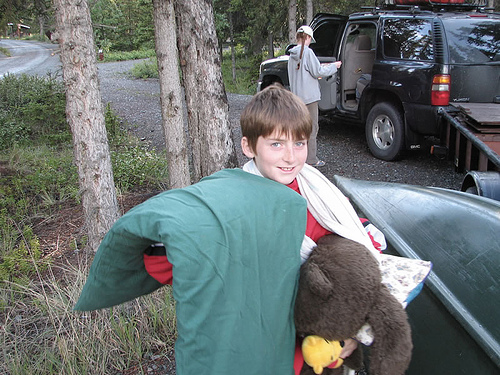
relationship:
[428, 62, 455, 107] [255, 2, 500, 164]
lights on van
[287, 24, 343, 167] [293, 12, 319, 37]
girl wearing hat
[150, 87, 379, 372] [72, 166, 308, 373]
boy holding pillow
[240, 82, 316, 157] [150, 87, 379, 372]
hair on boy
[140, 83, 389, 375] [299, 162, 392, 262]
boy has sheet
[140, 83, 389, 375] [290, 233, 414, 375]
boy holding bear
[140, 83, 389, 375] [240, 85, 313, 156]
boy with hair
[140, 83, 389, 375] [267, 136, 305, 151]
boy with blue eyes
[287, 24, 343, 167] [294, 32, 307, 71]
girl with braided hair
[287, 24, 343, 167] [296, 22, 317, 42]
girl wearing hat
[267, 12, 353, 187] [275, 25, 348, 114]
girl wearing sweater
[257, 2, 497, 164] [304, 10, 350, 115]
van with door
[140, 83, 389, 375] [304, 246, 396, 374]
boy with bear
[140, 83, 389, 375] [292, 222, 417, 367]
boy holding bear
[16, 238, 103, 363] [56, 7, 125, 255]
grass by tree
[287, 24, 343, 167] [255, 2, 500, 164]
girl by van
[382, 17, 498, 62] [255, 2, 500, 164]
windows on van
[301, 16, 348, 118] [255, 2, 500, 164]
door on van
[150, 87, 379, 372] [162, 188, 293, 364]
boy holding pillow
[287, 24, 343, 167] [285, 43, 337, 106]
girl wearing sweater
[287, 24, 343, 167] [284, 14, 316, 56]
girl wearing hat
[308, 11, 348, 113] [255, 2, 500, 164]
door open on van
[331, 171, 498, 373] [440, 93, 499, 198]
boat on trailer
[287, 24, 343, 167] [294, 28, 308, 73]
girl with braided hair